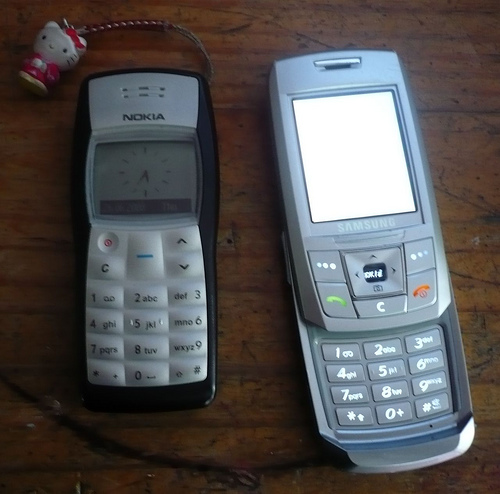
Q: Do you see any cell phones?
A: Yes, there is a cell phone.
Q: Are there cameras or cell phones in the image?
A: Yes, there is a cell phone.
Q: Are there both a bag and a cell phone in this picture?
A: No, there is a cell phone but no bags.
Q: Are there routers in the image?
A: No, there are no routers.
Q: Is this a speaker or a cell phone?
A: This is a cell phone.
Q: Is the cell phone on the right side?
A: Yes, the cell phone is on the right of the image.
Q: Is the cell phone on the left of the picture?
A: No, the cell phone is on the right of the image.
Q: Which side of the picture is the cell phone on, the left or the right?
A: The cell phone is on the right of the image.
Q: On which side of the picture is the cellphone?
A: The cellphone is on the right of the image.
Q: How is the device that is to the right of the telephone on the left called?
A: The device is a cell phone.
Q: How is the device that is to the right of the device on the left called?
A: The device is a cell phone.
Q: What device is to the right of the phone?
A: The device is a cell phone.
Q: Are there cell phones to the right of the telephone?
A: Yes, there is a cell phone to the right of the telephone.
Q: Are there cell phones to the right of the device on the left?
A: Yes, there is a cell phone to the right of the telephone.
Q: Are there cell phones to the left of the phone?
A: No, the cell phone is to the right of the phone.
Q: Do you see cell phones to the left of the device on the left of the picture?
A: No, the cell phone is to the right of the phone.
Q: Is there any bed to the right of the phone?
A: No, there is a cell phone to the right of the phone.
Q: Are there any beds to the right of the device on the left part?
A: No, there is a cell phone to the right of the phone.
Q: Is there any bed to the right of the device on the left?
A: No, there is a cell phone to the right of the phone.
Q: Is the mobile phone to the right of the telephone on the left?
A: Yes, the mobile phone is to the right of the telephone.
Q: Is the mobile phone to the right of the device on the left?
A: Yes, the mobile phone is to the right of the telephone.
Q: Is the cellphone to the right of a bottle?
A: No, the cellphone is to the right of the telephone.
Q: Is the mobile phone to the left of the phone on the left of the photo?
A: No, the mobile phone is to the right of the phone.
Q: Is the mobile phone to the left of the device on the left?
A: No, the mobile phone is to the right of the phone.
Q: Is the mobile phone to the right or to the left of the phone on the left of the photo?
A: The mobile phone is to the right of the telephone.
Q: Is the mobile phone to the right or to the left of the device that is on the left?
A: The mobile phone is to the right of the telephone.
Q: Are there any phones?
A: Yes, there is a phone.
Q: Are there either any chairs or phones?
A: Yes, there is a phone.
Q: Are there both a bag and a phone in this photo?
A: No, there is a phone but no bags.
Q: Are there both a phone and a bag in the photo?
A: No, there is a phone but no bags.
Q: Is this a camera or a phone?
A: This is a phone.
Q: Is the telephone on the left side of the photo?
A: Yes, the telephone is on the left of the image.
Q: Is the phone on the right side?
A: No, the phone is on the left of the image.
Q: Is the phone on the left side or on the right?
A: The phone is on the left of the image.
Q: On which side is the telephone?
A: The telephone is on the left of the image.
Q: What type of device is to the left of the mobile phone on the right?
A: The device is a phone.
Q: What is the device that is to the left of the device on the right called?
A: The device is a phone.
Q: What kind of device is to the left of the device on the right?
A: The device is a phone.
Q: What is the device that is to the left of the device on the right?
A: The device is a phone.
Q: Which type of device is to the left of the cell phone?
A: The device is a phone.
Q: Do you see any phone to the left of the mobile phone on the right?
A: Yes, there is a phone to the left of the cellphone.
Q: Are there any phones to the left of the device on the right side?
A: Yes, there is a phone to the left of the cellphone.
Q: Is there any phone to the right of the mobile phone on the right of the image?
A: No, the phone is to the left of the cell phone.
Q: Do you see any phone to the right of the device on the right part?
A: No, the phone is to the left of the cell phone.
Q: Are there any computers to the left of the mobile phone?
A: No, there is a phone to the left of the mobile phone.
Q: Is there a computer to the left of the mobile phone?
A: No, there is a phone to the left of the mobile phone.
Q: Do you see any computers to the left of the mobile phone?
A: No, there is a phone to the left of the mobile phone.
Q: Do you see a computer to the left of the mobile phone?
A: No, there is a phone to the left of the mobile phone.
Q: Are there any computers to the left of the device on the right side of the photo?
A: No, there is a phone to the left of the mobile phone.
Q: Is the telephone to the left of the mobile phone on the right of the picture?
A: Yes, the telephone is to the left of the cell phone.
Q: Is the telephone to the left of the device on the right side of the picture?
A: Yes, the telephone is to the left of the cell phone.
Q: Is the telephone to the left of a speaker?
A: No, the telephone is to the left of the cell phone.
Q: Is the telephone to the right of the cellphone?
A: No, the telephone is to the left of the cellphone.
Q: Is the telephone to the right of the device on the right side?
A: No, the telephone is to the left of the cellphone.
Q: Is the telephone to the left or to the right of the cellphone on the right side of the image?
A: The telephone is to the left of the cell phone.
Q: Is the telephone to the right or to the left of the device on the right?
A: The telephone is to the left of the cell phone.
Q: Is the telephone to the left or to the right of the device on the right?
A: The telephone is to the left of the cell phone.